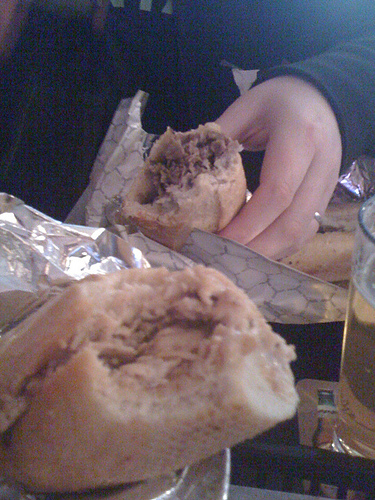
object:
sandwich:
[0, 262, 300, 499]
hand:
[214, 72, 349, 267]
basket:
[228, 439, 375, 496]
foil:
[0, 195, 149, 308]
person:
[0, 0, 375, 266]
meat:
[138, 304, 214, 351]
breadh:
[217, 377, 286, 443]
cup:
[327, 195, 375, 458]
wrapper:
[0, 193, 151, 301]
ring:
[314, 210, 324, 224]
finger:
[185, 95, 343, 298]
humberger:
[125, 119, 249, 242]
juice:
[334, 281, 375, 465]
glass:
[335, 191, 375, 462]